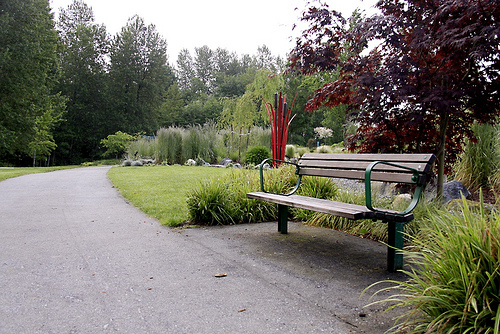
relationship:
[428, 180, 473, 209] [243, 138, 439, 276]
dark rock behind bench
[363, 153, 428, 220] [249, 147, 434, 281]
armrest on bench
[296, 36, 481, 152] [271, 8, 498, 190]
buds on tree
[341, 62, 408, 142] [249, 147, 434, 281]
tree behind bench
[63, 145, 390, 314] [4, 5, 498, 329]
path going through park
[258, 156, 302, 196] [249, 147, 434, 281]
armrest on bench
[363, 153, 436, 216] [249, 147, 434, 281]
armrest on bench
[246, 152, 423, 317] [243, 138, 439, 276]
leg on bench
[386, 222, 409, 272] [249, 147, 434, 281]
leg on bench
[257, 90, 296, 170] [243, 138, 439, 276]
spikey beyond bench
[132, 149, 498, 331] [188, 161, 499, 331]
grass around bench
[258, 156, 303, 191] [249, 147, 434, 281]
armrest on bench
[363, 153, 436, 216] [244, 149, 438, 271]
armrest on bench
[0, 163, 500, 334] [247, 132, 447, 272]
path near bench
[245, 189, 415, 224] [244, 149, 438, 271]
seat on bench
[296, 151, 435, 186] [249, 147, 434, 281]
slat on bench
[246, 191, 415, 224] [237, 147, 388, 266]
slat on bench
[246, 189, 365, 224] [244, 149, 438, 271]
slat on bench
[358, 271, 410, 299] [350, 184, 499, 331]
green leaf on bush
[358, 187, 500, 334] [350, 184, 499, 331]
green leaf on bush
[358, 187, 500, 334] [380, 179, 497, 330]
green leaf on bush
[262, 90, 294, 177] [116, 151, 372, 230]
spikey in grass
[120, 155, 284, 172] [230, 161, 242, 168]
row of stone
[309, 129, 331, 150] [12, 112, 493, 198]
person in distance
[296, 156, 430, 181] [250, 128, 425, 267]
slat on bench